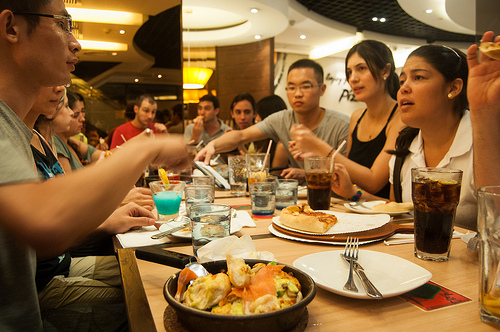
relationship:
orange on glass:
[150, 167, 169, 186] [142, 175, 186, 223]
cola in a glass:
[411, 172, 460, 258] [411, 165, 458, 262]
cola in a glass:
[300, 157, 331, 214] [476, 184, 498, 329]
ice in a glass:
[411, 177, 458, 215] [411, 165, 458, 262]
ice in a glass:
[305, 166, 332, 188] [476, 184, 498, 329]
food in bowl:
[180, 257, 297, 312] [157, 251, 320, 330]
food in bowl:
[180, 257, 297, 312] [142, 257, 330, 329]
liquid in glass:
[149, 190, 183, 216] [152, 177, 179, 215]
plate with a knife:
[293, 225, 431, 299] [355, 267, 379, 296]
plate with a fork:
[293, 225, 431, 299] [343, 235, 358, 291]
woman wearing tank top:
[330, 32, 403, 188] [342, 112, 394, 170]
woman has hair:
[330, 32, 403, 188] [353, 39, 398, 88]